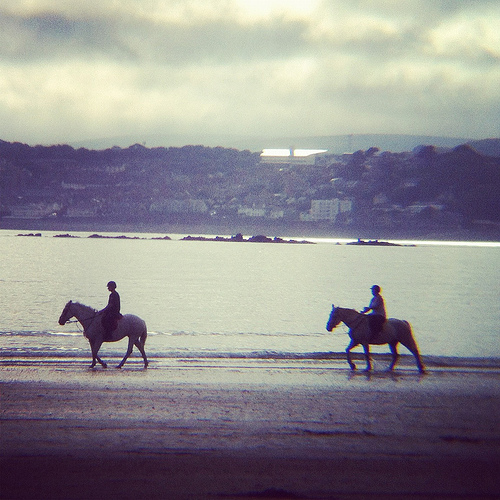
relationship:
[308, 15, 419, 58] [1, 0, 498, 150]
cloud in sky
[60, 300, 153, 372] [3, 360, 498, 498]
horse walking on beach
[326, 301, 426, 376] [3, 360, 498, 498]
horse walking on beach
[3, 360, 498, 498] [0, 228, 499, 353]
beach in front of water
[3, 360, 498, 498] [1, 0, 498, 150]
beach below sky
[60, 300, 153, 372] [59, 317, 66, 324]
horse has mouth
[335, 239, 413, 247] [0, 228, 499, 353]
island in water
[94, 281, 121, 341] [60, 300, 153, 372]
person riding on horse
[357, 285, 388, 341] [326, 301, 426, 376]
person riding on horse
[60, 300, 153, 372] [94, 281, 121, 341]
horse under person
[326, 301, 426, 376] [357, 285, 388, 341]
horse under person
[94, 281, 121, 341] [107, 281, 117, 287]
person wearing helmet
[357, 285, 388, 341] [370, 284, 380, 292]
person wearing helmet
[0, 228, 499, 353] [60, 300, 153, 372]
water behind horse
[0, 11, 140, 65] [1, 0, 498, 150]
cloud in sky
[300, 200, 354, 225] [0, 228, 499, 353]
building behind water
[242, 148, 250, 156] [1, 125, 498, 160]
tree on horizon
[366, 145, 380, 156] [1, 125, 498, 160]
tree on horizon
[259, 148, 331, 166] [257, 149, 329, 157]
building has roof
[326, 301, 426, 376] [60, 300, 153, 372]
horse following horse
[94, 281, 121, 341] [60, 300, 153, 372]
person riding horse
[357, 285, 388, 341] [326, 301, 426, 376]
person riding horse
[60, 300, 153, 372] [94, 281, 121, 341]
horse has person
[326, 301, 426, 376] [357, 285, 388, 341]
horse has person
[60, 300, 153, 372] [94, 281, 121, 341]
horse carrying person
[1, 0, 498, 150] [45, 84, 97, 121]
sky has cloud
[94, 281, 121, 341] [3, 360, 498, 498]
person on beach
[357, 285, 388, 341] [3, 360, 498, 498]
person above beach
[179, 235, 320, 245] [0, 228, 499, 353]
island in water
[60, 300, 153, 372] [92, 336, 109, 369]
horse has leg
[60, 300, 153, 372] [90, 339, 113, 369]
horse has leg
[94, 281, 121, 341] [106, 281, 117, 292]
person has head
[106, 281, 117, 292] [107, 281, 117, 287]
head has helmet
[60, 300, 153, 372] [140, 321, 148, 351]
horse has tail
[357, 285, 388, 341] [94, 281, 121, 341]
person riding behind person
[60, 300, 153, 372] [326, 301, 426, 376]
horse in front of horse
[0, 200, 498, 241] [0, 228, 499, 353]
shore behind water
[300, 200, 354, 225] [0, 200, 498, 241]
building on shore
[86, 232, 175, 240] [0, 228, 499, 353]
island in water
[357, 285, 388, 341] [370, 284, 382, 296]
person has head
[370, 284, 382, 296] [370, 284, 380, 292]
head wearing helmet